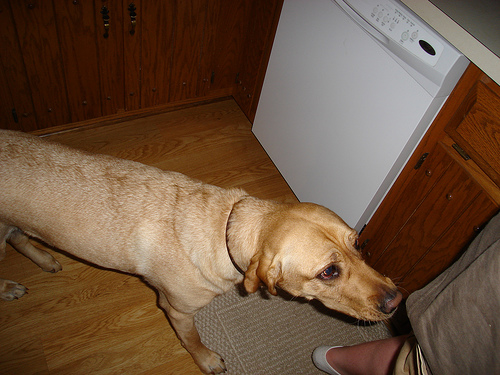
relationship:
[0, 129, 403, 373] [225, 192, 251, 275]
dog wearing collar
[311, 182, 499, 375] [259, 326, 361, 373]
person wearing shoes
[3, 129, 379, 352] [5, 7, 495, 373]
dog in kitchen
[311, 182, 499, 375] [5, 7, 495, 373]
person standing in kitchen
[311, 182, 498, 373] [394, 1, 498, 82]
person at kitchen counter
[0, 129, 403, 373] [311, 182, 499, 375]
dog standing behind person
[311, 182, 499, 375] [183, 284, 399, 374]
person on rug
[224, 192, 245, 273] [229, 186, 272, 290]
collar around dog's neck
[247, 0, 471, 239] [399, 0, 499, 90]
dishwasher under countertop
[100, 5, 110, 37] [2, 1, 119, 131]
handle on door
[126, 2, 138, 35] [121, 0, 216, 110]
handle on door